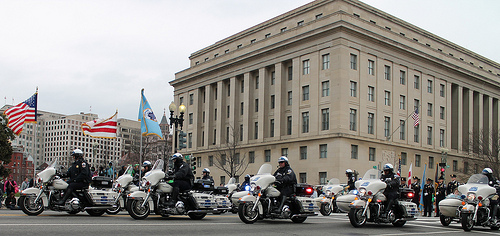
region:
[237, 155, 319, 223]
a police officer riding motorcycle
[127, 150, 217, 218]
a police officer riding motorcycle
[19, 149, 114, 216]
a police officer riding motorcycle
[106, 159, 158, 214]
a police officer riding motorcycle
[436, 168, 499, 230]
a police officer riding motorcycle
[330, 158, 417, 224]
a police officer riding motorcycle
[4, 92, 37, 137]
a waving American flag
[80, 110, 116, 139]
a waving red and white flag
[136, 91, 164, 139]
a waving blue flag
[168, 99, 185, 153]
ornate black street light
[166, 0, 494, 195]
A building in the background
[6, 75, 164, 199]
Three flags in the foreground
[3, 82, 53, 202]
An American flag waving in the air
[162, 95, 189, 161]
A street lamp in the background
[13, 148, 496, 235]
Police on white motorcycles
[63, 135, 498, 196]
Police are wearing white helmets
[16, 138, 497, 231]
Police motorcycles are white in color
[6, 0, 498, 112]
The sky is cloudy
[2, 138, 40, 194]
A brown colored building in the background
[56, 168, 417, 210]
Police are wearing dark colored outfits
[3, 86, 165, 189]
the flags on the side of the road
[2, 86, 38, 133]
the american flag on the pole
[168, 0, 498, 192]
the large cement building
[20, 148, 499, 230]
the police officer's riding on their motorcycles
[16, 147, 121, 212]
the motorcycle and rider on the road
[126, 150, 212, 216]
the motorcycle and rider on the road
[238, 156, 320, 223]
the motorcycle and rider on the road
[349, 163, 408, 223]
the motorcycle and rider on the road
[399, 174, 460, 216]
the police officers standing on the road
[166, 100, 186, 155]
the street light near the road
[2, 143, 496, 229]
long police motorcycle procession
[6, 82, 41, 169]
American flag flapping in breeze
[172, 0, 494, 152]
corner view of tan colored building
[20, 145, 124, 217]
one police officer on motorcycle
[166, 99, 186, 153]
two street lamps on black metal post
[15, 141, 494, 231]
police officers in parade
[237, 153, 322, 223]
man wearing white motorcycle helmet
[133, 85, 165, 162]
one light blue flag on pole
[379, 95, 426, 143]
one American flag on building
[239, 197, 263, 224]
one front motorcycle wheel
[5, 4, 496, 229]
a parade of motorcycle officers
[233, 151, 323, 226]
police officer sitting on motorcycle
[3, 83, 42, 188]
an American flag on sidewalk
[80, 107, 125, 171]
red and white striped flag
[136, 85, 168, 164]
light blue flag with yellow trim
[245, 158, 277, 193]
motorcycle windshield and fairing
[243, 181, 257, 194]
blue flashing headlights on motorcycle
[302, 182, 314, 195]
red flashing light on motorcycle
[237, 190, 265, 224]
motorcycle tire and fender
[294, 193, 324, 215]
a motorcycle hard saddlebag